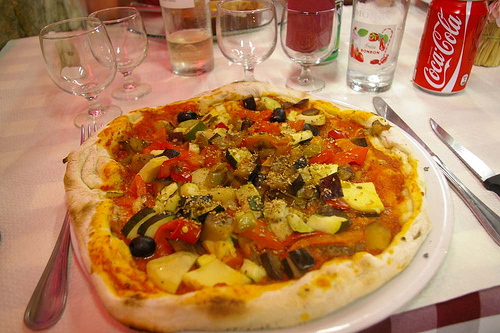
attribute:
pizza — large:
[63, 80, 430, 330]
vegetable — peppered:
[180, 194, 225, 221]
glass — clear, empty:
[38, 18, 118, 126]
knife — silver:
[431, 115, 500, 196]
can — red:
[412, 0, 489, 96]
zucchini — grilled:
[122, 207, 166, 242]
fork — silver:
[24, 122, 112, 329]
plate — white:
[65, 86, 454, 332]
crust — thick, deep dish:
[102, 254, 395, 332]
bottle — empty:
[346, 0, 410, 94]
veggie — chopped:
[205, 211, 234, 241]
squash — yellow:
[188, 260, 251, 289]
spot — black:
[422, 251, 430, 259]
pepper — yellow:
[198, 251, 217, 269]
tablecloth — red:
[360, 282, 499, 331]